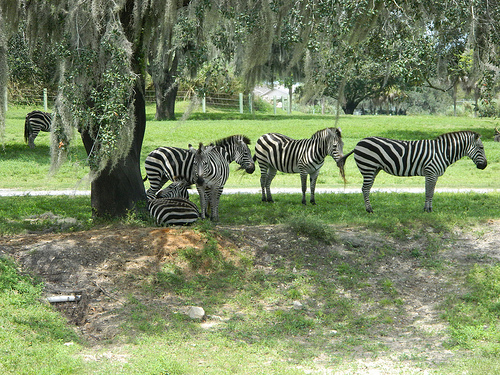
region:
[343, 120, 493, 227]
A Zebra Standing by himself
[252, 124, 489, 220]
Two Zebra's standing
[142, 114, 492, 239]
A group of Zebra's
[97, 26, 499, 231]
Zebra's under a tree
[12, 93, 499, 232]
Zebra's in a park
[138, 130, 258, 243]
A group of three Zebra's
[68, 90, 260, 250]
Zebra's near a tree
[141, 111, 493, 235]
Zebra's by a road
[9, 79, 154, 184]
A Zebra behind a tree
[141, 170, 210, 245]
A Zebra lying down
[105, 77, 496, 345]
Zebras are our standing in a field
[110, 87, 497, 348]
Zebras are standing in the shade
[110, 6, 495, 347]
Zebras are standing under a tree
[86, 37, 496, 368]
Zebras are looking for food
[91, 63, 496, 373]
Zebras are on a game reserve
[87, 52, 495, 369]
Five zebras are happily together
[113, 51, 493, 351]
One zebra is lying down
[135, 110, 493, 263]
Four zebras are standing up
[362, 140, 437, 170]
Stripes on a zebra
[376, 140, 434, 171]
Black and white stripes of a zebra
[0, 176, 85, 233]
black and white striped zebra in enclosure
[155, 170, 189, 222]
black and white striped zebra in enclosure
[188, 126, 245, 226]
black and white striped zebra in enclosure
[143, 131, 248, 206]
black and white striped zebra in enclosure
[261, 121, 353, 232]
black and white striped zebra in enclosure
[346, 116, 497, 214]
black and white striped zebra in enclosure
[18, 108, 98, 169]
black and white striped zebra in enclosure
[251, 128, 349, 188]
striped zebra in enclosure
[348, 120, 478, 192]
striped zebra in enclosure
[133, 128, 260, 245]
striped zebra in enclosure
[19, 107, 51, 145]
black and white striped zebra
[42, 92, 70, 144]
black and white striped zebra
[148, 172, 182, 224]
black and white striped zebra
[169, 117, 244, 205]
black and white striped zebra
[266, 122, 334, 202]
black and white striped zebra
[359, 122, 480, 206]
black and white striped zebra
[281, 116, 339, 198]
black and white striped zebra in enclosure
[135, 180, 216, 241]
black and white striped zebra in enclosure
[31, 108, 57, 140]
black and white striped zebra in enclosure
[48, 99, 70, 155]
black and white striped zebra in enclosure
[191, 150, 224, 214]
black and white striped zebra in enclosure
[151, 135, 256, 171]
black and white striped zebra in enclosure